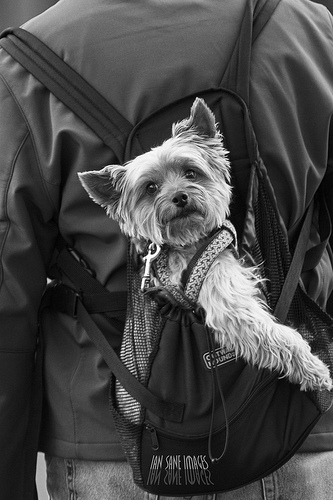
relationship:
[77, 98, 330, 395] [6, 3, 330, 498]
dog in backpack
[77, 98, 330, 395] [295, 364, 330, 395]
dog has a paw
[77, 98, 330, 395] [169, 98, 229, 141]
dog has an ear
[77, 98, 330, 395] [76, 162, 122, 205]
dog has an ear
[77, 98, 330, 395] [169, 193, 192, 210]
dog has a nose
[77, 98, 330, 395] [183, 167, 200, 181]
dog has an eye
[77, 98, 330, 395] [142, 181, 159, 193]
dog has an eye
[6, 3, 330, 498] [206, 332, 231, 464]
backpack has a cord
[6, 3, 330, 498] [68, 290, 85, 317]
backpack has a buckle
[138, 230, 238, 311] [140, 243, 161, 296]
leash has a clasp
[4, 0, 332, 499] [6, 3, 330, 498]
man carrying a backpack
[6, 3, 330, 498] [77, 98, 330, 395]
backpack holding dog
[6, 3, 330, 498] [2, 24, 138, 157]
backpack has a strap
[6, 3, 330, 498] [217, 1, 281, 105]
backpack has a strap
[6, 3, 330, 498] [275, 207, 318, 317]
backpack has a strap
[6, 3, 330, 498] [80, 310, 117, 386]
backpack has a strap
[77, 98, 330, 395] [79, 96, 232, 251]
dog turning head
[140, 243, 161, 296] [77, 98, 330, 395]
clasp on dog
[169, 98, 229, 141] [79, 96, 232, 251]
ear on head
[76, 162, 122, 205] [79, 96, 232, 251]
ear on head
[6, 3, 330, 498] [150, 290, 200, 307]
backpack has a tag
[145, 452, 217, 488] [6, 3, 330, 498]
words are on backpack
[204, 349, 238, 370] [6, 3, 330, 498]
words are on backpack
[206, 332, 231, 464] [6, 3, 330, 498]
cord on backpack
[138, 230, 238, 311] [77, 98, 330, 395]
leash on dog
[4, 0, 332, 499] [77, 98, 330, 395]
man carrying dog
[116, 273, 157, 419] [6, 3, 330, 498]
netting on backpack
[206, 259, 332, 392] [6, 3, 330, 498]
leg hanging outside of backpack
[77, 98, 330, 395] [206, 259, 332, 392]
dog has a leg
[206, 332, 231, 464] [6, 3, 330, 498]
cord hanging from backpack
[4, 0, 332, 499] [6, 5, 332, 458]
man wearing a jacket